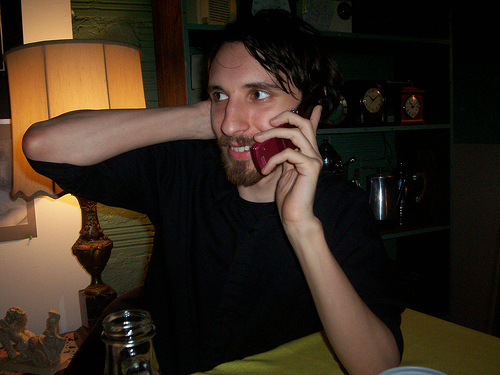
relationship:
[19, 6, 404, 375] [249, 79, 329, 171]
man on h cellphone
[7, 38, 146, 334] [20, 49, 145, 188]
lamp have shade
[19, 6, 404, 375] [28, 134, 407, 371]
man wearing shirt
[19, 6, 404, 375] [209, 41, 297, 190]
man has face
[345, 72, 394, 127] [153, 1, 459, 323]
clock on top of shelf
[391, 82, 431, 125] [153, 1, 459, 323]
clock on top of shelf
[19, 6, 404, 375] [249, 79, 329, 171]
man on cellphone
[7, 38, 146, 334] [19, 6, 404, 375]
lamp behind man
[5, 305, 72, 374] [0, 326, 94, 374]
statue on top of table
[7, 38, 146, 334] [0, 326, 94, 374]
lamp on top of table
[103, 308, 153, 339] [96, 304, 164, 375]
top from glass bottle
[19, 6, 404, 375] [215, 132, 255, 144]
man have mustache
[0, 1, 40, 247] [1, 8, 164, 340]
picture hanging on wall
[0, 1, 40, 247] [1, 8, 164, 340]
picture pinned to wall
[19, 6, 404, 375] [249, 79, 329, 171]
man holding cellphone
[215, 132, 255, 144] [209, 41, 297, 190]
mustache on face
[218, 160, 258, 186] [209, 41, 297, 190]
goatee on face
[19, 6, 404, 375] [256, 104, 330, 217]
man has hand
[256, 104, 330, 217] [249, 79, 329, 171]
hand against cellphone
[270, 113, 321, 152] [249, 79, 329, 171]
finger holding cellphone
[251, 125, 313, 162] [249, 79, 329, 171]
finger holding cellphone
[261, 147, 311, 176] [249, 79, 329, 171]
finger holding cellphone